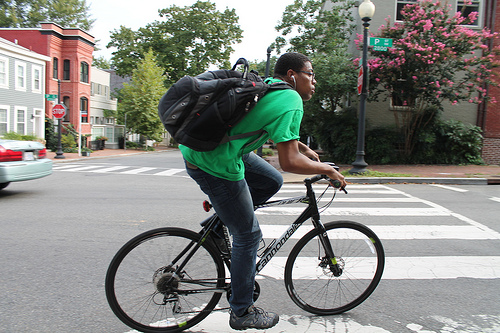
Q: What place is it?
A: It is a road.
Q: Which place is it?
A: It is a road.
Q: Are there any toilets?
A: No, there are no toilets.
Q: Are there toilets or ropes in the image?
A: No, there are no toilets or ropes.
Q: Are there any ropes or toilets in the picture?
A: No, there are no toilets or ropes.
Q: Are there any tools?
A: No, there are no tools.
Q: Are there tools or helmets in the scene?
A: No, there are no tools or helmets.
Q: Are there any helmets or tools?
A: No, there are no tools or helmets.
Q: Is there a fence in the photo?
A: No, there are no fences.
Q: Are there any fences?
A: No, there are no fences.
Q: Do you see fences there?
A: No, there are no fences.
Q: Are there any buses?
A: No, there are no buses.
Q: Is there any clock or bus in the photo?
A: No, there are no buses or clocks.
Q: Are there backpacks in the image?
A: Yes, there is a backpack.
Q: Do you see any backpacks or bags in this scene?
A: Yes, there is a backpack.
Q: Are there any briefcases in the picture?
A: No, there are no briefcases.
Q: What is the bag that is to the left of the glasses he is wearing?
A: The bag is a backpack.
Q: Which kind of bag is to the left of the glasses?
A: The bag is a backpack.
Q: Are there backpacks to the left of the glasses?
A: Yes, there is a backpack to the left of the glasses.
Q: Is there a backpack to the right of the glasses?
A: No, the backpack is to the left of the glasses.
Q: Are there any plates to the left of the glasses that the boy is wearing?
A: No, there is a backpack to the left of the glasses.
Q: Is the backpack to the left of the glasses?
A: Yes, the backpack is to the left of the glasses.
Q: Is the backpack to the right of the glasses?
A: No, the backpack is to the left of the glasses.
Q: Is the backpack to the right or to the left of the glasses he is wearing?
A: The backpack is to the left of the glasses.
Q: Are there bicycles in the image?
A: Yes, there is a bicycle.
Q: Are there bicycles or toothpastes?
A: Yes, there is a bicycle.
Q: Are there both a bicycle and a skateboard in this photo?
A: No, there is a bicycle but no skateboards.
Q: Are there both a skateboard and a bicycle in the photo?
A: No, there is a bicycle but no skateboards.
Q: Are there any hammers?
A: No, there are no hammers.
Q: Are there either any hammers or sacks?
A: No, there are no hammers or sacks.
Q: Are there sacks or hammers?
A: No, there are no hammers or sacks.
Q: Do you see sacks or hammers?
A: No, there are no hammers or sacks.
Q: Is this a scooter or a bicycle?
A: This is a bicycle.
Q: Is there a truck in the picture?
A: No, there are no trucks.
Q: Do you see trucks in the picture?
A: No, there are no trucks.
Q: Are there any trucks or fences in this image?
A: No, there are no trucks or fences.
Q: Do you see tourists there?
A: No, there are no tourists.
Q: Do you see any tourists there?
A: No, there are no tourists.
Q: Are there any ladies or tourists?
A: No, there are no tourists or ladies.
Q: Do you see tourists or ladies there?
A: No, there are no tourists or ladies.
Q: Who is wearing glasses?
A: The boy is wearing glasses.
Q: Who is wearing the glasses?
A: The boy is wearing glasses.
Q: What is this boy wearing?
A: The boy is wearing glasses.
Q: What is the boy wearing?
A: The boy is wearing glasses.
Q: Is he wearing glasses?
A: Yes, the boy is wearing glasses.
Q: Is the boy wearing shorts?
A: No, the boy is wearing glasses.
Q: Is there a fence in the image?
A: No, there are no fences.